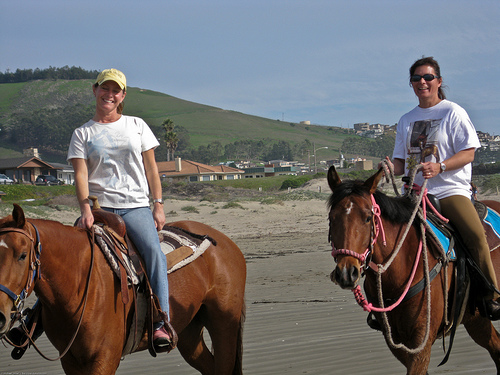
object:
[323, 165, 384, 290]
horse head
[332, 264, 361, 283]
nose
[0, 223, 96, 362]
bridle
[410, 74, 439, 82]
glasses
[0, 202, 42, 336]
harness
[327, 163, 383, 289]
harness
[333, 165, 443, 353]
bridle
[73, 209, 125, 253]
sadlle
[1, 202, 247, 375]
brown horse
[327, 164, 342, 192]
ear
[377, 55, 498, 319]
women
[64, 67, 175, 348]
women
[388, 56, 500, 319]
lady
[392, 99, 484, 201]
tee shirt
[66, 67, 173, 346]
lady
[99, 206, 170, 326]
jeans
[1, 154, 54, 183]
homes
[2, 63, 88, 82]
trees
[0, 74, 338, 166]
hill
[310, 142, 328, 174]
street light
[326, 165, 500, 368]
horse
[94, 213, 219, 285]
blanket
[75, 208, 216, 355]
saddle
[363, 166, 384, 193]
ear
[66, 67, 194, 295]
woman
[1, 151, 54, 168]
black roof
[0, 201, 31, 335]
head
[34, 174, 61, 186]
black car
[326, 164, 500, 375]
brown horse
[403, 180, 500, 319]
saddle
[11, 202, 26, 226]
ear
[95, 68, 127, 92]
cap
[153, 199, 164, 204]
watch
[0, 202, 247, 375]
horse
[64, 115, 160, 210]
tee shirt